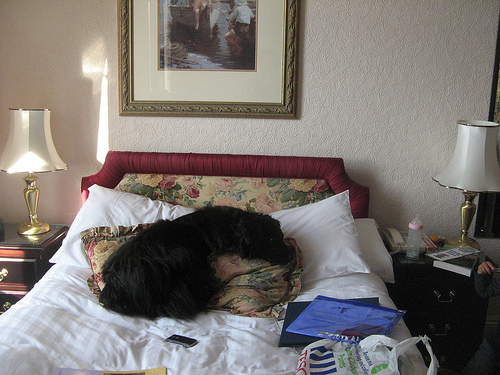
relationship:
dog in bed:
[99, 206, 294, 320] [1, 157, 463, 373]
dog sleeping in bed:
[99, 206, 294, 320] [1, 157, 463, 373]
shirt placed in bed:
[281, 280, 420, 362] [27, 154, 388, 374]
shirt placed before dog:
[280, 282, 410, 347] [99, 206, 294, 320]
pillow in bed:
[50, 181, 146, 237] [57, 290, 414, 373]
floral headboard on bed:
[78, 148, 373, 221] [1, 157, 463, 373]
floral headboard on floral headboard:
[80, 151, 370, 220] [80, 151, 370, 220]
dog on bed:
[105, 202, 298, 319] [1, 157, 463, 373]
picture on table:
[112, 1, 308, 124] [363, 37, 436, 97]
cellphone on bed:
[162, 332, 199, 353] [1, 147, 433, 373]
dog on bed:
[99, 206, 294, 320] [1, 147, 433, 373]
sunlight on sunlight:
[3, 103, 72, 203] [3, 103, 72, 203]